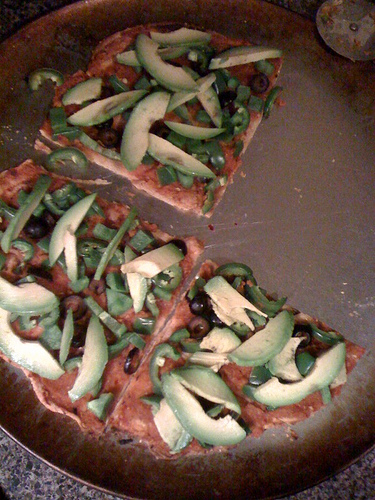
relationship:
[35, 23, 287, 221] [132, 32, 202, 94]
pizza has avocado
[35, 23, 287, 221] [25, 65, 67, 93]
pizza has jalapenos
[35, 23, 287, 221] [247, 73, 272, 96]
pizza has black olive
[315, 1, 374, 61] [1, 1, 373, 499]
pizza cutter on top of pizza pan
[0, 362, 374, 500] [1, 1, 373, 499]
burnt edge on top of pizza pan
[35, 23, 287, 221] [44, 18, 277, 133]
pizza has crust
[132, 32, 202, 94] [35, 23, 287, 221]
avocado on top of pizza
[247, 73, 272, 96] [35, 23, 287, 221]
black olive on top of pizza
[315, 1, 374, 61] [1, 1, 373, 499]
pizza cutter resting on pizza pan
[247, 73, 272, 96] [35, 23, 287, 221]
black olive on side of pizza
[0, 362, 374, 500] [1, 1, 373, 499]
burnt edge on side of pizza pan